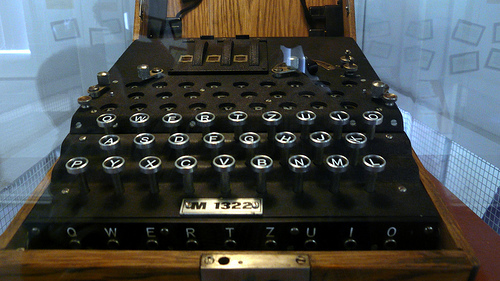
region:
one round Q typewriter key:
[92, 109, 117, 126]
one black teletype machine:
[16, 3, 455, 260]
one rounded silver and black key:
[248, 153, 274, 173]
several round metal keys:
[63, 155, 388, 176]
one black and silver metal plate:
[176, 192, 267, 215]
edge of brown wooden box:
[2, 245, 479, 275]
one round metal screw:
[201, 252, 215, 269]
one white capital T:
[223, 223, 236, 242]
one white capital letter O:
[378, 222, 400, 241]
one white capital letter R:
[183, 225, 197, 241]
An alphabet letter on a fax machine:
[65, 157, 85, 174]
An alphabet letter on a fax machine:
[106, 154, 123, 174]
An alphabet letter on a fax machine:
[366, 150, 383, 179]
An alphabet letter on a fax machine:
[265, 219, 274, 242]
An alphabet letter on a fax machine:
[387, 216, 395, 240]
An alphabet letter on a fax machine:
[198, 108, 214, 126]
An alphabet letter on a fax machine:
[244, 131, 262, 158]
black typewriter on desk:
[23, 33, 435, 253]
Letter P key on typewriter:
[63, 154, 88, 172]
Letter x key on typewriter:
[138, 152, 162, 172]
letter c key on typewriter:
[175, 152, 199, 174]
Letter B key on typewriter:
[249, 153, 273, 173]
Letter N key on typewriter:
[286, 151, 310, 174]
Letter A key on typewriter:
[96, 132, 123, 149]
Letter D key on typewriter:
[168, 128, 190, 148]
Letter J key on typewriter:
[313, 132, 332, 147]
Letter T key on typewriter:
[228, 108, 251, 125]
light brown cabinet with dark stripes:
[111, 2, 362, 63]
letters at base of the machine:
[51, 213, 403, 251]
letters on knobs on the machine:
[69, 108, 378, 186]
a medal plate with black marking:
[179, 189, 264, 221]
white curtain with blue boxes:
[411, 2, 488, 152]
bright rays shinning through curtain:
[3, 37, 48, 69]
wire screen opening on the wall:
[451, 132, 497, 214]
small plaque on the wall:
[79, 6, 115, 57]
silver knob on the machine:
[369, 69, 406, 115]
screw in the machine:
[294, 254, 322, 280]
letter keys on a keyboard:
[65, 111, 390, 194]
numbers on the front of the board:
[180, 197, 262, 215]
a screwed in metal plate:
[197, 253, 312, 278]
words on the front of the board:
[62, 220, 412, 250]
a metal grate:
[401, 116, 498, 226]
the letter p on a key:
[64, 157, 91, 170]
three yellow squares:
[175, 51, 251, 62]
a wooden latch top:
[131, 3, 355, 36]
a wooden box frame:
[0, 148, 485, 277]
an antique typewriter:
[0, 0, 482, 279]